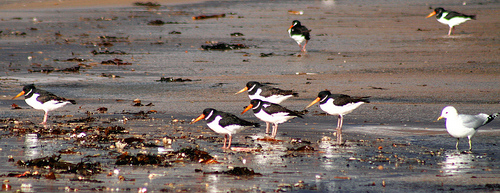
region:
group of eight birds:
[14, 2, 492, 166]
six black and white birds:
[14, 14, 374, 169]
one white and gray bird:
[433, 102, 493, 162]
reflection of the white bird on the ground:
[434, 146, 473, 176]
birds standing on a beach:
[10, 7, 497, 184]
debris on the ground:
[19, 140, 99, 187]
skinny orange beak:
[185, 107, 205, 132]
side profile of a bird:
[422, 4, 478, 41]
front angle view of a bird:
[276, 15, 328, 62]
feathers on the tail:
[464, 104, 499, 133]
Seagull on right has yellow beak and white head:
[434, 101, 499, 156]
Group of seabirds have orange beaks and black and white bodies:
[188, 74, 372, 151]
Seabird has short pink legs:
[331, 112, 348, 133]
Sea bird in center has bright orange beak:
[241, 99, 256, 116]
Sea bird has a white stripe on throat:
[299, 86, 341, 113]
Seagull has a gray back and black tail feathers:
[461, 109, 499, 131]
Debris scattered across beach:
[34, 17, 199, 75]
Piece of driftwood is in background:
[184, 10, 239, 23]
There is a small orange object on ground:
[371, 141, 388, 151]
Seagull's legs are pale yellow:
[453, 137, 475, 154]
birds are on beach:
[32, 2, 449, 163]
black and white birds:
[223, 81, 377, 166]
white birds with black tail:
[421, 100, 498, 161]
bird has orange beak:
[185, 106, 225, 135]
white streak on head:
[200, 106, 209, 128]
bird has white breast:
[203, 111, 255, 144]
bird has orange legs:
[207, 128, 246, 169]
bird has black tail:
[241, 122, 261, 137]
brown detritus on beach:
[81, 92, 215, 189]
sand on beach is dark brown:
[285, 0, 438, 160]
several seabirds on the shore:
[6, 4, 497, 188]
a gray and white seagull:
[429, 95, 499, 157]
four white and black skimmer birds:
[191, 61, 380, 168]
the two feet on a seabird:
[218, 127, 240, 155]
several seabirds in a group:
[178, 67, 382, 172]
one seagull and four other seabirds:
[193, 67, 496, 180]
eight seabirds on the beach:
[4, 0, 498, 153]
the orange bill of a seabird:
[301, 90, 326, 118]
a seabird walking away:
[278, 10, 322, 61]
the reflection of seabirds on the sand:
[184, 140, 384, 191]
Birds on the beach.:
[0, 0, 490, 185]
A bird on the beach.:
[5, 75, 70, 125]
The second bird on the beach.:
[185, 95, 260, 160]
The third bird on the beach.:
[240, 90, 290, 140]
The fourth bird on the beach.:
[230, 65, 295, 105]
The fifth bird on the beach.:
[300, 80, 370, 125]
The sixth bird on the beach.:
[275, 15, 320, 65]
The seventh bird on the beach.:
[425, 85, 495, 150]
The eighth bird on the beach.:
[415, 1, 485, 46]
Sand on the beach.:
[342, 45, 447, 75]